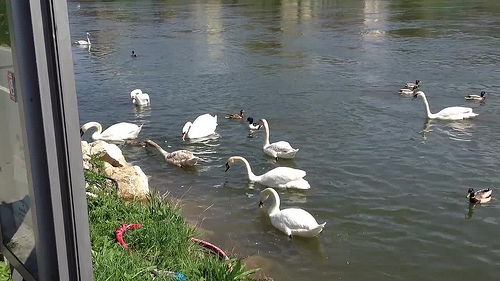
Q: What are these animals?
A: Swans.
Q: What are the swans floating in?
A: Water.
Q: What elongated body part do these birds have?
A: Necks.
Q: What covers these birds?
A: Feathers.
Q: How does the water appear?
A: Murky and dark.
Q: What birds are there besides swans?
A: Ducks.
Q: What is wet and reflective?
A: The water.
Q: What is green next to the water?
A: Grass.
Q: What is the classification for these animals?
A: Fowl.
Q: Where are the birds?
A: On the water.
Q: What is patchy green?
A: Grass.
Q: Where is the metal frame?
A: On a door.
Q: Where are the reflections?
A: On the water.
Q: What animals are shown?
A: Swans.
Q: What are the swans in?
A: Lake.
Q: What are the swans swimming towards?
A: Bank.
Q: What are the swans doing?
A: Swimming.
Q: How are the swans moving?
A: Swimming.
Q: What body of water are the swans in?
A: Lake.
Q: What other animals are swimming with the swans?
A: Ducks.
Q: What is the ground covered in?
A: Grass.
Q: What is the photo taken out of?
A: Window.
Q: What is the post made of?
A: Metal.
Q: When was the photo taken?
A: Daytime.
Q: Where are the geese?
A: Water.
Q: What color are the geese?
A: White.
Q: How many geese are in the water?
A: Nine.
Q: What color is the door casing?
A: Gray.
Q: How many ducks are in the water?
A: Six.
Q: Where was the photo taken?
A: Water.